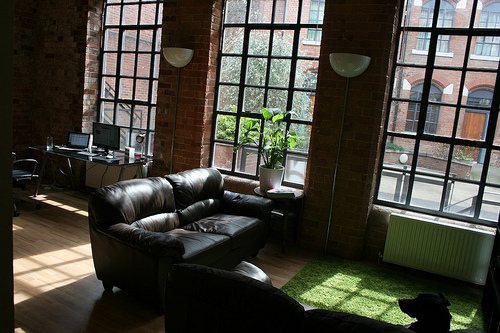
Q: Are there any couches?
A: Yes, there is a couch.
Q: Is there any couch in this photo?
A: Yes, there is a couch.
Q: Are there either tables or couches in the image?
A: Yes, there is a couch.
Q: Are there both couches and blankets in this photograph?
A: No, there is a couch but no blankets.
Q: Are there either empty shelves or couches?
A: Yes, there is an empty couch.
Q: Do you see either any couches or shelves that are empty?
A: Yes, the couch is empty.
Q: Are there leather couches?
A: Yes, there is a couch that is made of leather.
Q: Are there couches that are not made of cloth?
A: Yes, there is a couch that is made of leather.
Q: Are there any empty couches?
A: Yes, there is an empty couch.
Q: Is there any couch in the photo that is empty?
A: Yes, there is a couch that is empty.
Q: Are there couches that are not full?
A: Yes, there is a empty couch.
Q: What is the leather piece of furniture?
A: The piece of furniture is a couch.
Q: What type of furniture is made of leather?
A: The furniture is a couch.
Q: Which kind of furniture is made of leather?
A: The furniture is a couch.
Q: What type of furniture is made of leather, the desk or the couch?
A: The couch is made of leather.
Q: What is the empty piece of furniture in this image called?
A: The piece of furniture is a couch.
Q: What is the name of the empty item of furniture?
A: The piece of furniture is a couch.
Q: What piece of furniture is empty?
A: The piece of furniture is a couch.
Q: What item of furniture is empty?
A: The piece of furniture is a couch.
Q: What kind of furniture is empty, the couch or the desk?
A: The couch is empty.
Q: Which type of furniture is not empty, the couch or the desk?
A: The desk is not empty.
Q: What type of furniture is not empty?
A: The furniture is a desk.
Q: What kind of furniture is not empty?
A: The furniture is a desk.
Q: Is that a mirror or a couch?
A: That is a couch.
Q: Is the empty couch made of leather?
A: Yes, the couch is made of leather.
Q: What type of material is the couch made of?
A: The couch is made of leather.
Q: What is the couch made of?
A: The couch is made of leather.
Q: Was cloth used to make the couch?
A: No, the couch is made of leather.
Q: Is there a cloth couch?
A: No, there is a couch but it is made of leather.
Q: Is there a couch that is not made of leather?
A: No, there is a couch but it is made of leather.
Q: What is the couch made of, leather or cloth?
A: The couch is made of leather.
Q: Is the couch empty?
A: Yes, the couch is empty.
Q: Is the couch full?
A: No, the couch is empty.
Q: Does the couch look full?
A: No, the couch is empty.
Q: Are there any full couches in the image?
A: No, there is a couch but it is empty.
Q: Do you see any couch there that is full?
A: No, there is a couch but it is empty.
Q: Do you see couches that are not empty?
A: No, there is a couch but it is empty.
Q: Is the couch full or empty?
A: The couch is empty.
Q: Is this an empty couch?
A: Yes, this is an empty couch.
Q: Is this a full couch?
A: No, this is an empty couch.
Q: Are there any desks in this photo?
A: Yes, there is a desk.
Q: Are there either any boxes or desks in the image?
A: Yes, there is a desk.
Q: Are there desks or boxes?
A: Yes, there is a desk.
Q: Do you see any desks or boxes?
A: Yes, there is a desk.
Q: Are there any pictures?
A: No, there are no pictures.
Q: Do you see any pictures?
A: No, there are no pictures.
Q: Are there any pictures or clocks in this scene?
A: No, there are no pictures or clocks.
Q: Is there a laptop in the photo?
A: Yes, there is a laptop.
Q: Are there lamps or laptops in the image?
A: Yes, there is a laptop.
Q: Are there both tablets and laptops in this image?
A: No, there is a laptop but no tablets.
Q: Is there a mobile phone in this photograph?
A: No, there are no cell phones.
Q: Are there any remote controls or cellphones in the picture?
A: No, there are no cellphones or remote controls.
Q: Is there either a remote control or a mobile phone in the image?
A: No, there are no cell phones or remote controls.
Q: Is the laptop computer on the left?
A: Yes, the laptop computer is on the left of the image.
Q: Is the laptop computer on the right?
A: No, the laptop computer is on the left of the image.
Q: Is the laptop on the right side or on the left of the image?
A: The laptop is on the left of the image.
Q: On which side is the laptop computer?
A: The laptop computer is on the left of the image.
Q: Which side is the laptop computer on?
A: The laptop computer is on the left of the image.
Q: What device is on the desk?
A: The device is a laptop.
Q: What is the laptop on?
A: The laptop is on the desk.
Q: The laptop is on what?
A: The laptop is on the desk.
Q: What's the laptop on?
A: The laptop is on the desk.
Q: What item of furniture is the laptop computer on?
A: The laptop computer is on the desk.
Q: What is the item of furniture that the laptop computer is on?
A: The piece of furniture is a desk.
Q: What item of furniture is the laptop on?
A: The laptop computer is on the desk.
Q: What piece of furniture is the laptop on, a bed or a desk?
A: The laptop is on a desk.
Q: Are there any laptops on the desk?
A: Yes, there is a laptop on the desk.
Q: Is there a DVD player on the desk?
A: No, there is a laptop on the desk.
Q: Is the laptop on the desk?
A: Yes, the laptop is on the desk.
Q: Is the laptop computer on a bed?
A: No, the laptop computer is on the desk.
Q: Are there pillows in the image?
A: No, there are no pillows.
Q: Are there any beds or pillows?
A: No, there are no pillows or beds.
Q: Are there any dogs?
A: Yes, there is a dog.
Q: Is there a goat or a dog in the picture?
A: Yes, there is a dog.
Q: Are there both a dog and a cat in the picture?
A: No, there is a dog but no cats.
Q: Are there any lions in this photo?
A: No, there are no lions.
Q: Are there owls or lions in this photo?
A: No, there are no lions or owls.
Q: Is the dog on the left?
A: No, the dog is on the right of the image.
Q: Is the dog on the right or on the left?
A: The dog is on the right of the image.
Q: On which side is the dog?
A: The dog is on the right of the image.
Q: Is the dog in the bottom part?
A: Yes, the dog is in the bottom of the image.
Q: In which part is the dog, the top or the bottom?
A: The dog is in the bottom of the image.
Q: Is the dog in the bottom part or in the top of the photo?
A: The dog is in the bottom of the image.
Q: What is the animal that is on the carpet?
A: The animal is a dog.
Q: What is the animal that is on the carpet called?
A: The animal is a dog.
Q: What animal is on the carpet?
A: The animal is a dog.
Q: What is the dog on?
A: The dog is on the carpet.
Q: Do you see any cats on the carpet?
A: No, there is a dog on the carpet.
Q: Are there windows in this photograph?
A: Yes, there is a window.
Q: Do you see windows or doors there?
A: Yes, there is a window.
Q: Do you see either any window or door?
A: Yes, there is a window.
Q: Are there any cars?
A: No, there are no cars.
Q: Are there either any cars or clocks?
A: No, there are no cars or clocks.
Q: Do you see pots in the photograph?
A: Yes, there is a pot.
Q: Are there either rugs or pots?
A: Yes, there is a pot.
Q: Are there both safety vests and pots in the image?
A: No, there is a pot but no safety jackets.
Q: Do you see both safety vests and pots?
A: No, there is a pot but no safety jackets.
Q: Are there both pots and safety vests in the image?
A: No, there is a pot but no safety jackets.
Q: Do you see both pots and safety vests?
A: No, there is a pot but no safety jackets.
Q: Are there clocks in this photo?
A: No, there are no clocks.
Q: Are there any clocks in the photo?
A: No, there are no clocks.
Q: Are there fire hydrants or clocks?
A: No, there are no clocks or fire hydrants.